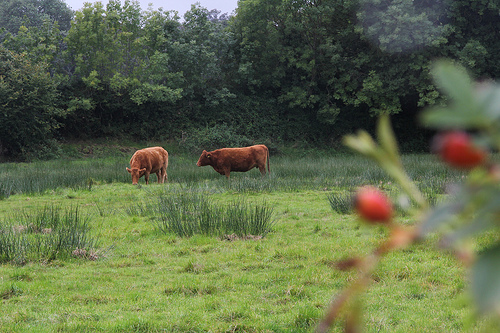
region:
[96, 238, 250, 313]
part of green grass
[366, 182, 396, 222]
part of a red flower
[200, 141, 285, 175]
part of a brown cow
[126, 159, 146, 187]
head of a cow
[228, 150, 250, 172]
stomach of a cow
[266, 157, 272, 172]
tail of a cow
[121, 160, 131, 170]
right ear of a cow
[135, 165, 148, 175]
left ear of a cow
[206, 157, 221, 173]
neck of a cow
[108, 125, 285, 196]
picture of two brown cows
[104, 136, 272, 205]
Two cows standing in a field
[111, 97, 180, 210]
Cow bending down to eat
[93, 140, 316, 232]
Cows are brown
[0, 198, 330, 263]
Tall green grass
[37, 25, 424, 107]
Many trees behind cows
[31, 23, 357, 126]
Trees have green leaves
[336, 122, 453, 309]
Bush has red flowers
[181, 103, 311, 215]
Cow looking at other cow bending down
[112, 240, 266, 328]
Shorter green grass next to tall grass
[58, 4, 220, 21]
Sky is blue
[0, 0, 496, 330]
A photo of animals in the field.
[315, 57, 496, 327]
A plant with red flowers.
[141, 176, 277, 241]
A patch of tall grass.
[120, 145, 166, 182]
A brown cow grazing.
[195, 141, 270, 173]
A brown cow staring at the other.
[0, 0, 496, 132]
A group of trees.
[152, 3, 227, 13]
A bright blue sky.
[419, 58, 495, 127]
A blurred green leaf.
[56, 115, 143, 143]
A dark area within the trees.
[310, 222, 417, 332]
A reddish branch of the plant.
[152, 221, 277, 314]
part of some green grass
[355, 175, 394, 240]
a small red flower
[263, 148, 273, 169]
tail of a cow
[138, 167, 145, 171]
left ear of a cow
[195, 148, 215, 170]
head of a cow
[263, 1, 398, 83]
part of a bushy tree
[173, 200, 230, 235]
part of taller grass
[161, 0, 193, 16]
part of the sky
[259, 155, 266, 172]
left hip of a cow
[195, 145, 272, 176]
red brown cows standing in the field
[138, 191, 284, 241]
green grass on the field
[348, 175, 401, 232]
red plant in out of focus picture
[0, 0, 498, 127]
green trees behind the cows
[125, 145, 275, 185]
two cows in a field alone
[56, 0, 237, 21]
grey sky in the background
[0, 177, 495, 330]
green field with dirt and cows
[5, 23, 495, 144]
a row of green trees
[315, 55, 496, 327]
out of focus red plant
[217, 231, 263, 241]
brown dirt on the field